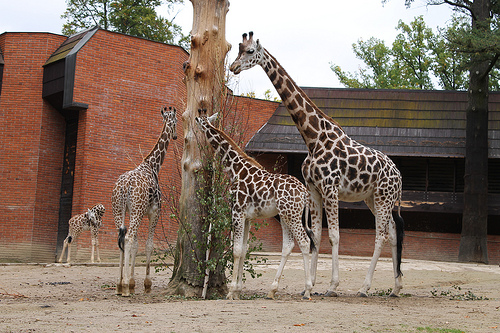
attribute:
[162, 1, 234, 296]
tree trunk — bark free, branchless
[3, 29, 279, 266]
building — brick, red, large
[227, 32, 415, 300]
giraffe — tallest, large, full grown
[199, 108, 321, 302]
giraffe — young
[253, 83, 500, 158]
roof — brown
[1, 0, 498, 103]
sky — white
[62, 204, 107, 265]
giraffe — smallest, small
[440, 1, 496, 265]
tree trunk — dark brown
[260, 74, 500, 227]
building — wooden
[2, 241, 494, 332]
ground — dirt